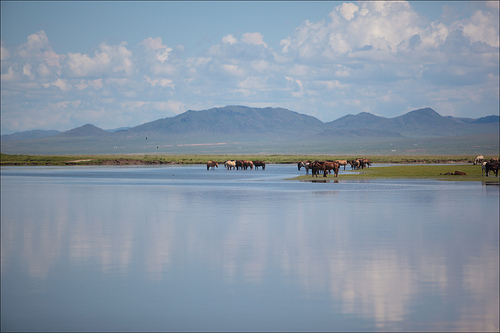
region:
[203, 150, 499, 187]
Wild animals standing in the forest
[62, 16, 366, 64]
A blue color sky with clouds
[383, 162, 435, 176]
Green color grass near the water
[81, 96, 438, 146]
Big mountain near the river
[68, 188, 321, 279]
River near the mountain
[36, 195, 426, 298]
Reflection of the clouds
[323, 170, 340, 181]
Legs of the wild animal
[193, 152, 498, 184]
Brown, black and white color of the wild animals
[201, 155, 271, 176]
Wild animals standing inside the river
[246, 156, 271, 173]
Wild animals drinking water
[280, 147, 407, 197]
several horses standing near water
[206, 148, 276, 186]
several horses standing water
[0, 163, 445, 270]
a large body of water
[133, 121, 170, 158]
two birds flying in the air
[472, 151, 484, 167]
a white horse next to the water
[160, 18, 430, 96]
white clouds in the sky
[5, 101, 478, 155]
mountains covered with trees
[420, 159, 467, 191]
a horse laying down on the ground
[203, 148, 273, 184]
several horses drinking water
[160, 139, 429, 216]
several horses in and near water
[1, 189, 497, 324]
reflection of clouds on water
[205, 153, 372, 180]
wild horses standing in water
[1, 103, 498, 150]
hazy mountains in distance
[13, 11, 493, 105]
puffy white clouds in sky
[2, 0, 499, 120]
blue sky with puffy white clouds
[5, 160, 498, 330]
calm blue water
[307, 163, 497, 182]
green grass bordering water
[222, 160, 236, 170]
tall white horse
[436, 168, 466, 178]
horse laying on grass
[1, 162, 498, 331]
Blue water with reflections on it.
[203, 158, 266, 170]
A bunch of horses gathered in the water.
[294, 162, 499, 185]
A small portion of green land in the water.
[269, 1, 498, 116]
Larger white cloud area over the horses.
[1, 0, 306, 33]
Blue sky above the clouds.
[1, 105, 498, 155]
All of the mountain range in the distance.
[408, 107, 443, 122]
The highest mountain peak in the distance.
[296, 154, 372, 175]
Largest group of horses on the land.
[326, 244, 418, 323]
Brightest white reflection on the water.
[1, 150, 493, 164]
Green land in the distance.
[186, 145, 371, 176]
group of horse grazing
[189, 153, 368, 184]
group of horse standing together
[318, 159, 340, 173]
brown horse standing in field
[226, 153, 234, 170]
white horse standing in water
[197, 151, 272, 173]
group of horses standing in water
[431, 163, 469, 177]
clump of wood on grass field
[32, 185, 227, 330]
large body of water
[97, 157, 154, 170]
brown shoreline of water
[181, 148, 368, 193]
horses standing in wet land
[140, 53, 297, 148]
clouds and mountains in background